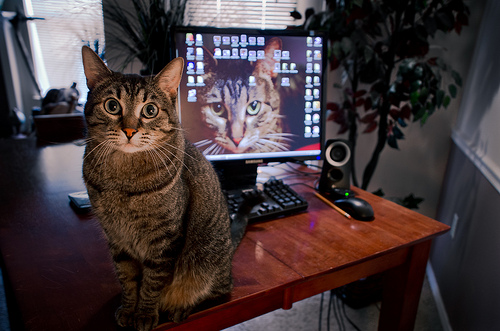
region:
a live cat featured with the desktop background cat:
[68, 9, 343, 329]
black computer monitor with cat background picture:
[179, 30, 321, 163]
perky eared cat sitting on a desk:
[73, 39, 238, 329]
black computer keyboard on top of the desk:
[223, 187, 318, 225]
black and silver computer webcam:
[318, 133, 350, 191]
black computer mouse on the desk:
[341, 190, 375, 220]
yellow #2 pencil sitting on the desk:
[309, 186, 352, 224]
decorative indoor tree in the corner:
[296, 8, 481, 205]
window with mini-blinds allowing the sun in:
[28, 4, 112, 111]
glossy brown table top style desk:
[15, 153, 445, 292]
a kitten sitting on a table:
[82, 45, 262, 328]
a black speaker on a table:
[321, 135, 351, 198]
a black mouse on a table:
[333, 194, 375, 221]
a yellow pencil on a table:
[309, 186, 350, 220]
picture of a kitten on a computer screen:
[187, 40, 293, 150]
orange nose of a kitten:
[121, 125, 131, 135]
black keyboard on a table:
[216, 176, 302, 218]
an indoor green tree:
[290, 1, 470, 306]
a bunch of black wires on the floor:
[316, 292, 353, 328]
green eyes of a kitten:
[101, 95, 158, 120]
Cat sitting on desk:
[81, 42, 231, 320]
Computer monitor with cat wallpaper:
[178, 25, 321, 160]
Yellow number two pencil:
[309, 189, 350, 221]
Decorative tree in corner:
[288, 1, 465, 208]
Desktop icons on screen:
[183, 30, 321, 138]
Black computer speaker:
[321, 140, 351, 199]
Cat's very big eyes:
[101, 93, 161, 122]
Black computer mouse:
[336, 196, 372, 219]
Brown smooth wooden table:
[10, 134, 446, 329]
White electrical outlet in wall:
[447, 212, 459, 240]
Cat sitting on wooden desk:
[75, 40, 236, 330]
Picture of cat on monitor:
[188, 39, 289, 154]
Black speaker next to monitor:
[319, 135, 352, 190]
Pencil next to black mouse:
[311, 188, 353, 221]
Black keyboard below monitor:
[224, 177, 306, 227]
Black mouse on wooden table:
[335, 194, 373, 219]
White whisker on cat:
[161, 138, 199, 164]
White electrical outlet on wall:
[447, 210, 460, 237]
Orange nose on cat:
[122, 127, 137, 139]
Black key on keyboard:
[270, 203, 282, 212]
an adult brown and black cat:
[78, 43, 230, 323]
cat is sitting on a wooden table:
[1, 43, 447, 328]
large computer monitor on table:
[177, 22, 326, 184]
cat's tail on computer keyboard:
[226, 176, 306, 243]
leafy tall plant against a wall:
[289, 1, 476, 309]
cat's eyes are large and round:
[102, 95, 159, 120]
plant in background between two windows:
[22, 0, 290, 105]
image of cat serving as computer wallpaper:
[181, 29, 323, 154]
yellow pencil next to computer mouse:
[307, 186, 373, 223]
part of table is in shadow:
[0, 154, 107, 329]